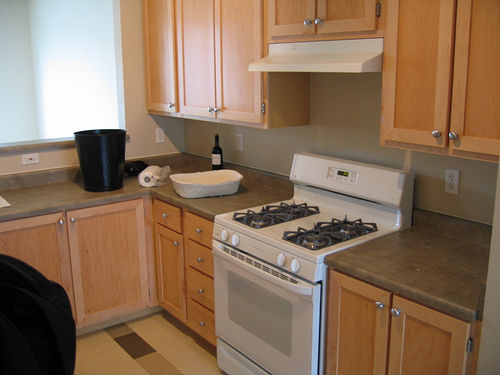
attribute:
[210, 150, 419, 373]
gas range — white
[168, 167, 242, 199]
container — white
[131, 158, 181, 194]
towels — paper, white, roll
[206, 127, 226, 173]
bottle — dark, wine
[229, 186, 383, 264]
burners — black, four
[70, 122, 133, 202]
bucket — black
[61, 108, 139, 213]
bucket — black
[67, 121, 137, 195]
bucket — black 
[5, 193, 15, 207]
sink — top 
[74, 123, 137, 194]
bucket — black 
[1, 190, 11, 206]
sink — top 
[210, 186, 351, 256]
burner — gas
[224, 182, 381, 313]
gas range — white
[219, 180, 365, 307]
gas range — white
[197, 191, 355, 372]
gas range — white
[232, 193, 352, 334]
gas range — white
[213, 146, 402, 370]
stove — overhead light , recepticle , white 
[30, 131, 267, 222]
countertop — wine , bottle 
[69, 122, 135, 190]
basket — small black waste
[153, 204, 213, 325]
drawers — four brown wooden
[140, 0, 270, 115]
cabinets — kitchen, set 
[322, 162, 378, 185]
display — electronic 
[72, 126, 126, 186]
can — black kitchen trash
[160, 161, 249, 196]
dish — white casserole 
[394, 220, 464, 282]
top — brown granite counter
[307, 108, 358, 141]
wall — electrical socket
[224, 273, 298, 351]
door — white oven , glass window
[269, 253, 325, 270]
knobs — round silver cabinet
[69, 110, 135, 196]
bucket — black 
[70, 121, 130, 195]
bucket — black 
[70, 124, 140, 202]
bucket — black 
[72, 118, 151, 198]
bucket — black 